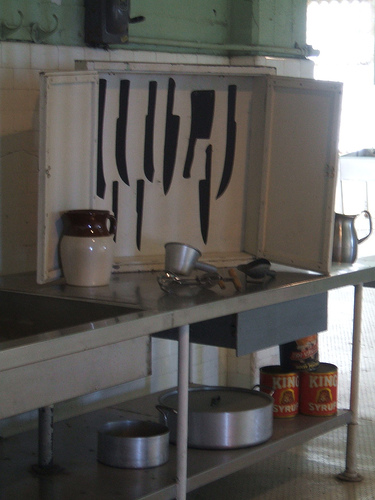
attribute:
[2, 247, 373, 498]
table — large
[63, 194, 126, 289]
jar — brown, tan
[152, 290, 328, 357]
drawer — gray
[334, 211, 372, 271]
pitcher — silver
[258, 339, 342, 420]
cans — large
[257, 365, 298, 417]
can — stacked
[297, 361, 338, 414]
can — stacked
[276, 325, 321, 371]
can — stacked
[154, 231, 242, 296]
pot — large, copper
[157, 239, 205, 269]
pot — small, metal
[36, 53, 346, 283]
box — white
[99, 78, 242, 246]
knives — black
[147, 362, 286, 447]
pan — large, sauce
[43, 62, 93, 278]
cabinet —  opened white 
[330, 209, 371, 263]
pitcher — metal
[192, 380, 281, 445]
metal pot — large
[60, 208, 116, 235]
brown area — dark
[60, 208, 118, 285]
pitcher — brown, white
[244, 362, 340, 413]
canned goods —  neatly stacked,  colorful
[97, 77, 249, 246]
case — white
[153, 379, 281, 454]
pot — large, stainless steel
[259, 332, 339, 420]
cans — large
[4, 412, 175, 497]
shelf —   lower 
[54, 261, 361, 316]
shelf — bottom